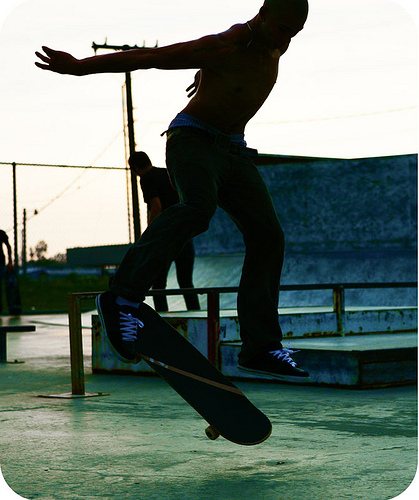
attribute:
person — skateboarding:
[34, 0, 319, 383]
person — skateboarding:
[122, 145, 210, 314]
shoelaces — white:
[116, 306, 145, 347]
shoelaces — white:
[265, 343, 302, 370]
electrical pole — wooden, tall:
[89, 36, 162, 250]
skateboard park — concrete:
[0, 153, 416, 499]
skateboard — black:
[111, 293, 277, 449]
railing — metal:
[63, 275, 418, 400]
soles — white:
[91, 294, 123, 364]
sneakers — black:
[89, 286, 313, 389]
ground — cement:
[4, 300, 417, 499]